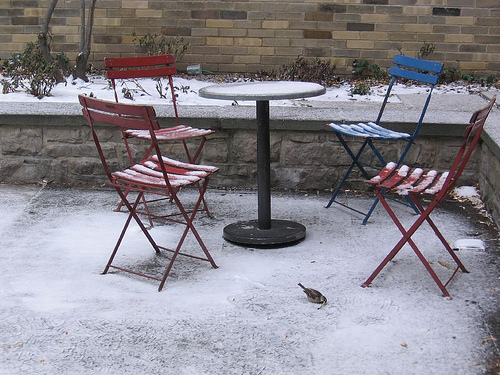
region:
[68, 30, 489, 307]
four chairs dusted with snow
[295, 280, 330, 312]
bird pecking in the snow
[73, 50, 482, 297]
three red chairs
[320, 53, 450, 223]
one blue chair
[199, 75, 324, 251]
black table dusted with snow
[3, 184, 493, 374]
dusting of snow on the cement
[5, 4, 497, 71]
brick wall behind table and chairs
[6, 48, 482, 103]
bushes cropping up through snow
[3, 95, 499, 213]
stone wall around table and chairs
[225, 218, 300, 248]
round base of black table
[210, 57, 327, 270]
a round table outside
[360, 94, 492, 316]
a red metal folding chair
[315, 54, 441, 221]
a blue metal folding chair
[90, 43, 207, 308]
two red folding chairs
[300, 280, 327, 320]
a bird on the ground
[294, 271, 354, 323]
a bird standing in the snow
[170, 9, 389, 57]
the side of a brick building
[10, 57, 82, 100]
a plant growing in a flower bed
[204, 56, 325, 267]
a small round table with snow on it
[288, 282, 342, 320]
a bird with a twig in its mouth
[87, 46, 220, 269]
two red chairs by the table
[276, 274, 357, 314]
bird on the ground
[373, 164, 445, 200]
snow on the chair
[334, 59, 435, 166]
a blue chair by the wall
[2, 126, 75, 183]
wall is made of brick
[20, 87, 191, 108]
snow on top of ledge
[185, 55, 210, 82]
electrical outlet in the wall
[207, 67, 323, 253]
round table in the middle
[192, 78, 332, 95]
snow on the table top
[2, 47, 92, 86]
green shrub in the snow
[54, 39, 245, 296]
two red chairs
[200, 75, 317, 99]
snow on the table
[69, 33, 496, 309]
four chairs around the table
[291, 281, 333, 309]
bird on the ground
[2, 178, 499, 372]
thin layer of snow on the ground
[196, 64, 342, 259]
small round table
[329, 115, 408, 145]
snow on the seat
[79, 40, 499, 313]
three red chairs and one blue chair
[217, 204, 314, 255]
round base of the table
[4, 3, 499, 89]
wall is made of brick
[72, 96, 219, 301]
chair in the snow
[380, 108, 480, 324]
chair in the snow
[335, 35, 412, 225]
chair in the snow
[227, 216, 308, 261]
base of the table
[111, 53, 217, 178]
chair in the snow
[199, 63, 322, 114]
top of the table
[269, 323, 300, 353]
patch of snow on the ground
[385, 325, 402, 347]
patch of snow on the ground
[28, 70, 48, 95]
bush on the ground